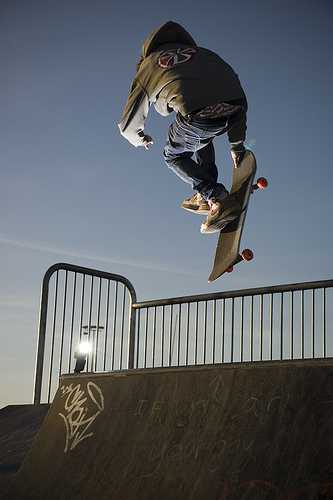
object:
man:
[118, 20, 268, 283]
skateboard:
[208, 149, 268, 283]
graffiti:
[57, 380, 104, 453]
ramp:
[0, 358, 332, 499]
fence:
[34, 262, 332, 403]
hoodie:
[117, 20, 248, 153]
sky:
[0, 0, 333, 409]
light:
[74, 340, 91, 373]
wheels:
[257, 176, 268, 189]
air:
[263, 127, 329, 282]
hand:
[231, 150, 241, 171]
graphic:
[157, 47, 198, 68]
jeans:
[162, 107, 244, 202]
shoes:
[199, 194, 241, 234]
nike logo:
[211, 204, 223, 216]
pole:
[135, 279, 333, 310]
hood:
[142, 20, 198, 60]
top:
[60, 357, 333, 378]